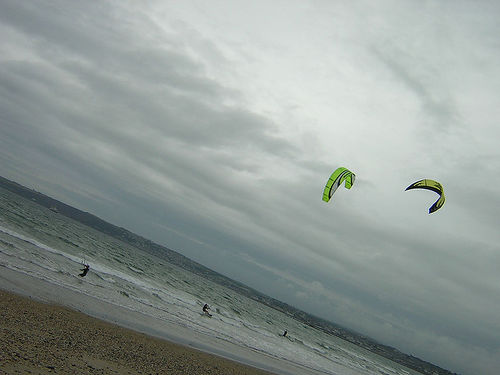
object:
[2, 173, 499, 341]
ocean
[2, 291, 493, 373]
sandy beach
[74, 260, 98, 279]
person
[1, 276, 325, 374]
beach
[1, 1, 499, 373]
gray sky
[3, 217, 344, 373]
wave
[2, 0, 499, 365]
sky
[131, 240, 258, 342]
waves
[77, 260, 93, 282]
person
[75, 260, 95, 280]
person/water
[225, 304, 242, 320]
wave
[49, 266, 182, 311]
water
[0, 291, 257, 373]
shore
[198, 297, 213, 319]
person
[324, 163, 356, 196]
parasail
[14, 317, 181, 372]
sand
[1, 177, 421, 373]
water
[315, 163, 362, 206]
green kite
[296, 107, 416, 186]
sky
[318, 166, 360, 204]
kite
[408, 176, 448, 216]
kite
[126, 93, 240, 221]
sky